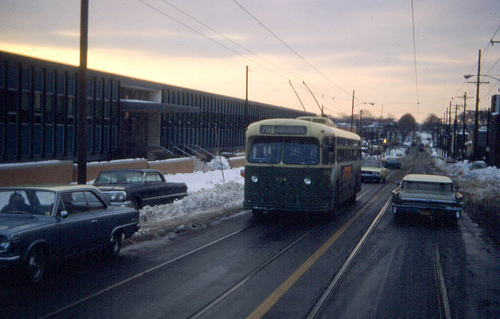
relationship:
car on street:
[2, 184, 139, 284] [1, 131, 499, 312]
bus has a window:
[242, 116, 364, 215] [284, 140, 318, 166]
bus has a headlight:
[242, 116, 364, 215] [304, 177, 312, 187]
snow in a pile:
[430, 141, 500, 240] [463, 160, 498, 185]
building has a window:
[2, 46, 317, 187] [53, 71, 67, 99]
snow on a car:
[430, 141, 500, 240] [2, 184, 139, 284]